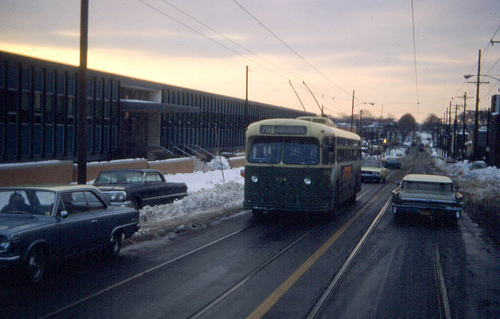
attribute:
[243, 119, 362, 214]
trolley — yellow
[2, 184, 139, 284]
car — driving, dark, black, blue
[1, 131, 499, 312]
street — icy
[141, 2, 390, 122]
lines — overhead, painted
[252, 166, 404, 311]
stripe — yellow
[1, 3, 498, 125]
sky — grey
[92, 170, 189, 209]
car — parked, black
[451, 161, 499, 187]
bank — large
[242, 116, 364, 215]
bus — green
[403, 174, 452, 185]
roof — white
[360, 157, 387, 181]
car — yellow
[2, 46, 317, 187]
building — yellow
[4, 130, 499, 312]
road — wet, yellow